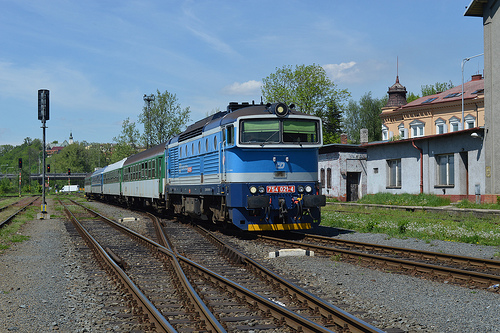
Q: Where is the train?
A: On the tracks.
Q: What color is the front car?
A: Blue.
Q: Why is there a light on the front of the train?
A: To light the way when it's dark.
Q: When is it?
A: Day time.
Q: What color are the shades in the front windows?
A: Green.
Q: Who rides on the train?
A: Passengers.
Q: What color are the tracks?
A: Brown.